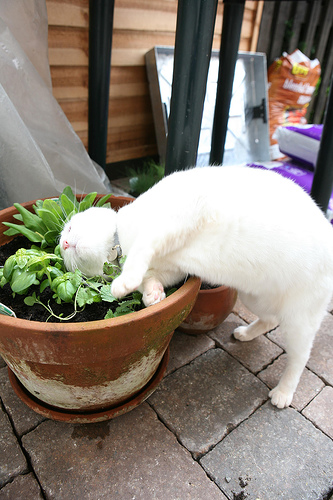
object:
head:
[60, 206, 116, 282]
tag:
[107, 244, 123, 262]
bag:
[267, 50, 321, 165]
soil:
[13, 295, 31, 315]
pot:
[1, 191, 201, 424]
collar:
[114, 211, 123, 256]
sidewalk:
[2, 171, 333, 500]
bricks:
[192, 390, 333, 498]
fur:
[139, 164, 333, 281]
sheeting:
[0, 0, 265, 169]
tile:
[197, 395, 333, 500]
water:
[71, 405, 109, 447]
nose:
[62, 239, 69, 250]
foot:
[267, 383, 294, 408]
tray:
[143, 46, 272, 166]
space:
[193, 395, 271, 463]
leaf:
[13, 201, 48, 236]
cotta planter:
[0, 184, 191, 321]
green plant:
[0, 186, 178, 320]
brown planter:
[0, 192, 202, 423]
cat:
[39, 160, 333, 410]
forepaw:
[141, 276, 168, 308]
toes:
[154, 292, 160, 301]